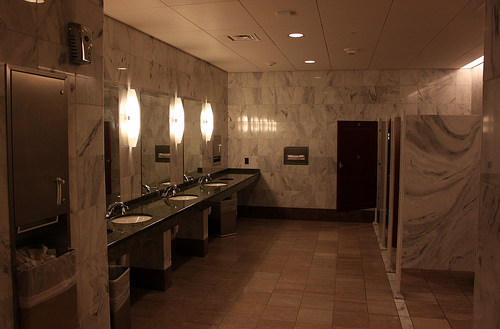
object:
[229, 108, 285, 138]
relection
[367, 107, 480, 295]
urinal partitions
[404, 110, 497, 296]
bathroom stalls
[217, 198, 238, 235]
trash can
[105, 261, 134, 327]
trash can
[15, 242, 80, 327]
trash can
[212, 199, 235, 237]
plastic bag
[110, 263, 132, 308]
plastic bag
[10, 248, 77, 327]
plastic bag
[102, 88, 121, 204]
mirror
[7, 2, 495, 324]
bathroom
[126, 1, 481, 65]
ceiling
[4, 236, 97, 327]
trash can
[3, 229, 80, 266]
garbage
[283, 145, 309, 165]
dispenser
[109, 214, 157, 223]
basins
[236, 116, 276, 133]
light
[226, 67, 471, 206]
marble wall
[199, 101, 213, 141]
light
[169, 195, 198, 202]
wash basins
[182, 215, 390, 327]
brown tile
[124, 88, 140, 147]
light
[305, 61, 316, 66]
light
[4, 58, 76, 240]
towel dispenser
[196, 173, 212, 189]
faucet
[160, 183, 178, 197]
faucet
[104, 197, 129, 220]
faucet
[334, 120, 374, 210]
door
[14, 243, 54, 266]
bag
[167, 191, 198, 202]
wash basin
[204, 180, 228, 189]
wash basin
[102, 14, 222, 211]
wall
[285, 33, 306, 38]
light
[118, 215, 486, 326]
floor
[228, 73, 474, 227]
wall